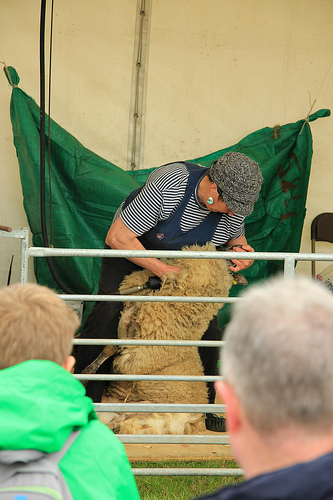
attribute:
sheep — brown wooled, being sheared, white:
[95, 240, 248, 433]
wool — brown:
[89, 397, 209, 435]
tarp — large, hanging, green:
[2, 65, 332, 373]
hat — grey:
[205, 151, 267, 219]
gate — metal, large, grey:
[1, 227, 332, 477]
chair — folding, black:
[310, 210, 333, 275]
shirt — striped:
[110, 160, 250, 248]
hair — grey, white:
[213, 267, 332, 438]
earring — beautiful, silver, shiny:
[204, 194, 216, 208]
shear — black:
[117, 275, 164, 295]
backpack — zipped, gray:
[0, 412, 88, 500]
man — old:
[193, 269, 331, 500]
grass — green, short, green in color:
[128, 458, 246, 500]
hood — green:
[0, 357, 98, 455]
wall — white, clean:
[1, 2, 333, 290]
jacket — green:
[0, 357, 147, 498]